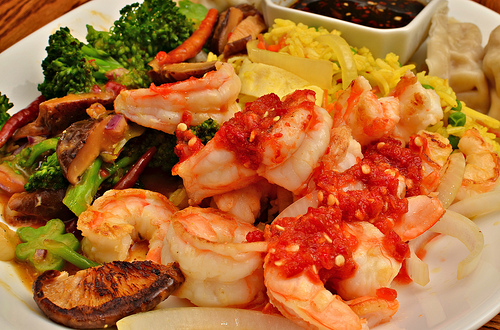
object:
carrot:
[256, 33, 290, 50]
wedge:
[34, 255, 179, 328]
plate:
[396, 270, 496, 329]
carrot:
[158, 7, 219, 66]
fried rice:
[257, 15, 500, 154]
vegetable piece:
[10, 216, 86, 276]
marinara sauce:
[215, 89, 320, 169]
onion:
[319, 31, 359, 89]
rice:
[257, 19, 404, 90]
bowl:
[1, 0, 497, 330]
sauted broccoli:
[36, 0, 195, 101]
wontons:
[412, 13, 493, 108]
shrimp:
[183, 93, 426, 330]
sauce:
[285, 0, 433, 29]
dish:
[0, 2, 499, 329]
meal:
[0, 0, 499, 330]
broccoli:
[36, 5, 183, 94]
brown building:
[286, 29, 366, 91]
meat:
[71, 185, 183, 257]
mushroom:
[28, 257, 180, 329]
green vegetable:
[10, 217, 93, 271]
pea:
[441, 105, 470, 147]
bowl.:
[261, 0, 447, 67]